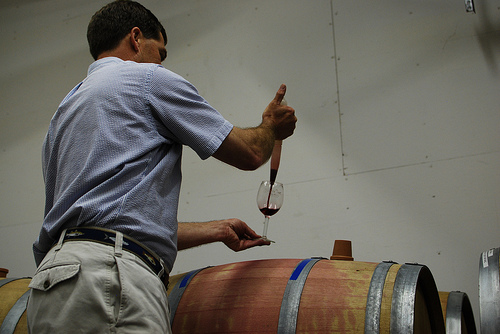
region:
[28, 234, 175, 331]
man wearing khaki pants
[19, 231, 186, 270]
man wearing patterned belt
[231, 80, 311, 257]
man pouring red wine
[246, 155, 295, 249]
man falling in wine glass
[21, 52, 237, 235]
man wearing a collared shirt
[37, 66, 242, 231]
man wearing a blue shirt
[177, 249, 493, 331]
wooden wine barrel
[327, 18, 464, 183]
white wall of room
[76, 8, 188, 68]
man with short black hair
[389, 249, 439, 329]
metal rim of barrel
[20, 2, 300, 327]
man pouring wine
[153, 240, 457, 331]
wooden barrel full of wine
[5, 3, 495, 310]
walls are plain and white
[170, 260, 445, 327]
barrel is rung with metal rings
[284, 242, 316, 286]
blue tag on wooden barrel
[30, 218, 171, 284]
man is wearing a black belt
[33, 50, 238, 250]
man wearing a light blue shirt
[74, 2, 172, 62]
man has short brown hair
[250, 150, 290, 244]
wine glass with wine being poured into it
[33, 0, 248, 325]
man in a short sleeve blue shirt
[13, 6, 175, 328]
man wearing a blue shirt and khaki pants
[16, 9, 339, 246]
man getting a sample of wine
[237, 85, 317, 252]
sample of red wine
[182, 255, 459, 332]
a wine stained wine barrel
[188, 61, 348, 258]
man getting a sample of red wine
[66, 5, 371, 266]
getting ready to test wine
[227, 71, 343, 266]
man putting wine in a wine glass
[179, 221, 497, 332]
wine barrels formenting wine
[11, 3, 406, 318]
man working in a wine making store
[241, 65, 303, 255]
man pouring wine in glass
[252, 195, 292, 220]
red wine in glass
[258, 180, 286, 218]
transparent wine glass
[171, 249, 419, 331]
brown wooden wine barrel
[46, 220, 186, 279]
man wearing a patterned belt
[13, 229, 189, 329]
man wearing a khaki pants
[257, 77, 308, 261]
man squeezing wine into glass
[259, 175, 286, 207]
red wine falling in glass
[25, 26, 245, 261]
man wearing blue shirt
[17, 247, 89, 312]
pants has back pocket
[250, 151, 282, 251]
wine glass has thick stem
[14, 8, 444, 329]
man standing in front of barrel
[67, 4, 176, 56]
man has dark hair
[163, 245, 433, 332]
barrel is light brown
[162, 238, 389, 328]
barrel has red stain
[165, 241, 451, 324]
barrel has silver trim